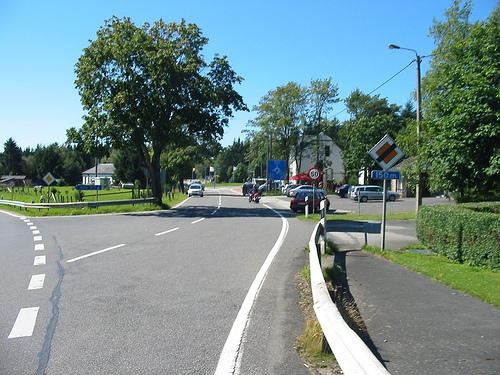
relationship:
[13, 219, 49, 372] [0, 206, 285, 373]
line on road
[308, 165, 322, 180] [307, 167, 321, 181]
number on number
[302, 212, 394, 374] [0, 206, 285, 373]
barricade on road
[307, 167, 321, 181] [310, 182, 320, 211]
number on pole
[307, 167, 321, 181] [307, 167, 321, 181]
number for number